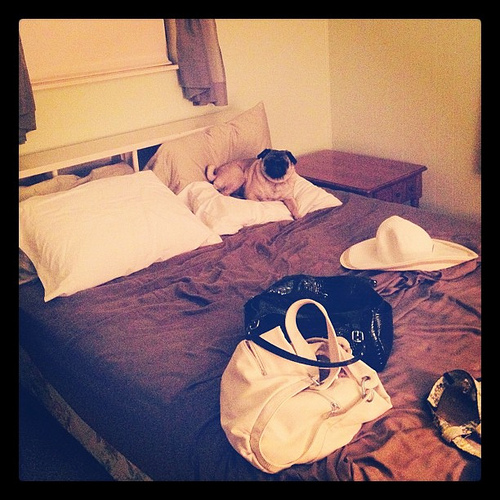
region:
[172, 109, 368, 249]
"The pug is laying on the pillows"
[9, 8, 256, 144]
"The window has a blind and a curtain"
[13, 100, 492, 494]
"A picture of a bed"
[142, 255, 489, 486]
"There are purses on the bed"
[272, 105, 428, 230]
"There is a small table beside the bed"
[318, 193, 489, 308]
"There is a hat on the bed"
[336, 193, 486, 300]
"The hat is white"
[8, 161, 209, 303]
"The pillow is white"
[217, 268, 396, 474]
"One of the purses are white"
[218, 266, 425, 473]
"One of the purses are black"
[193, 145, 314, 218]
the dog on the pillow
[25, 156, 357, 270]
the pillows on the bed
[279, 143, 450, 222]
the table beside the bed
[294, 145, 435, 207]
the table is wooden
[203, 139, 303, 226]
the dog is black and white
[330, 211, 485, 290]
a hat on the bed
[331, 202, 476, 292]
the hat is white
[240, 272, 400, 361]
a black purse on the bed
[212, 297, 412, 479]
a white purse on the bed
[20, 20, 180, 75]
the shades are down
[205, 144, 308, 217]
A pug on a pillow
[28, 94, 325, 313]
Four pillows on a bed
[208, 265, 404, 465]
Two bags on the bed.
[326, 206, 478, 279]
White hat on the bed.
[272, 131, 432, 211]
Wooden night stand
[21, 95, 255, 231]
Bookshelf headboard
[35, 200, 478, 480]
The blanket is brown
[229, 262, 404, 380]
Black bag on a bed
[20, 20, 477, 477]
Nobody shown in the photo.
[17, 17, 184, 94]
Window above the window.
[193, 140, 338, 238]
dog is laying on bed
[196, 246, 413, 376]
black purse is on bed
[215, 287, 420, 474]
white purse is on bed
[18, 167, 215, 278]
the pillow is white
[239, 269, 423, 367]
the bag is shiny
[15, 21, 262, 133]
the curtains are open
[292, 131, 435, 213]
the end table is brown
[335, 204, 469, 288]
a hat is on the bed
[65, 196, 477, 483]
the bed sheet is brown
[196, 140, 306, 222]
The dog is brown and black.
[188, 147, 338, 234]
The dog is laying on a pillow.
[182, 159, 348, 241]
The pillow is white.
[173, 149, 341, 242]
The pillow is rectangular.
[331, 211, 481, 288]
The hat is frumpy.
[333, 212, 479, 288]
The hat is white.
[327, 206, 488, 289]
The hat is rumpled.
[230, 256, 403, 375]
The purse is black.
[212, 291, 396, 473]
The purse is white.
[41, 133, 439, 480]
Two purses lying on the bed.